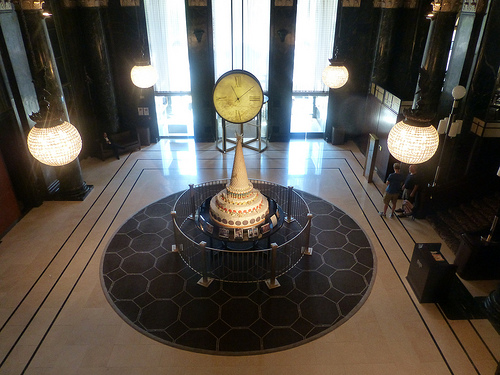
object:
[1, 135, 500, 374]
floor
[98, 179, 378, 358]
circle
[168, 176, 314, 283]
railing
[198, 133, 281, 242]
object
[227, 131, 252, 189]
cone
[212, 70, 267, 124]
clock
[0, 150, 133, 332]
triple lines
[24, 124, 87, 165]
lighted globe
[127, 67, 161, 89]
lighted globe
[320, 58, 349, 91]
lighted globe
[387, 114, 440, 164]
lighted globe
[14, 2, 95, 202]
column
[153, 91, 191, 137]
window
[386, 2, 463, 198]
column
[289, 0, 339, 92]
window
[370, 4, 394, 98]
column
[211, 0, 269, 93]
window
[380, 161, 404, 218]
person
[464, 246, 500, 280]
wall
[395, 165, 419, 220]
person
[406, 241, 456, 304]
reception desk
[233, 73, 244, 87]
number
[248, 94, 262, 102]
number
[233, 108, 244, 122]
number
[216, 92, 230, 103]
number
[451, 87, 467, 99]
light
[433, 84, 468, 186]
pole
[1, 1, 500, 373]
building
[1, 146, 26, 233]
door